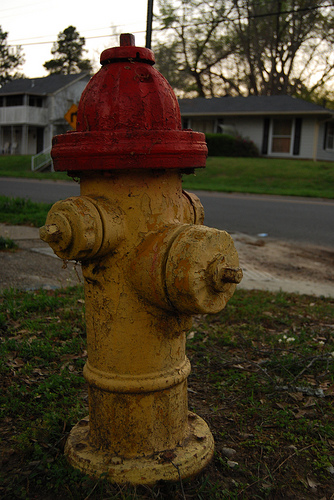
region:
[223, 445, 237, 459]
a dead leaf on the ground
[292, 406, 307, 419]
a dead leaf on the ground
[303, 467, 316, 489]
a dead leaf on the ground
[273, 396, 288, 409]
a dead leaf on the ground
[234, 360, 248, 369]
a dead leaf on the ground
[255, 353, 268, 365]
a dead leaf on the ground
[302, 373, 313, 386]
a dead leaf on the ground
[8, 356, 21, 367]
a dead leaf on the ground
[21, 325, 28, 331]
a dead leaf on the ground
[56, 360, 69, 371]
a dead leaf on the ground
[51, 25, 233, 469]
a red and yellow fire hydrant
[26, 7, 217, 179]
red top of a fire hydrant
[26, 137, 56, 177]
a white hand rail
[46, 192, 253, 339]
a fire hydrant with the paint coming off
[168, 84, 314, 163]
a white house with black shutters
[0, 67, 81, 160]
a two story house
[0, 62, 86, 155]
a house with two porches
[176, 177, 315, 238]
a paved road way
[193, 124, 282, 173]
a hedge bush in front of a house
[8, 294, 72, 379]
brown leaves on the ground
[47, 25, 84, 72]
a tree in a distance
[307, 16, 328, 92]
a tree in a distance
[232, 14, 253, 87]
a tree in a distance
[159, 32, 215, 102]
a tree in a distance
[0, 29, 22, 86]
a tree in a distance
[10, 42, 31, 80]
a tree in a distance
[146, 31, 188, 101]
a tree in a distance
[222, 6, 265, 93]
a tree in a distance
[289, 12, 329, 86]
a tree in a distance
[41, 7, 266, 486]
a fire hydrant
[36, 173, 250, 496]
Bottom portion of fire hydrant painted yellow.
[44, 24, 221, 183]
Top portion of fire hydrant painted red.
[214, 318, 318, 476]
Area on ground with grass, dirt and leaves.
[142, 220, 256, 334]
Portion of fire hydrant that accepts hose.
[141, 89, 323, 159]
Single story house with black shutters.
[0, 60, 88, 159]
Two story house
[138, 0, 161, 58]
Utility pole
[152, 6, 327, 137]
Trees behind house.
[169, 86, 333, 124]
Black shingled roof.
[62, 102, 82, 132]
Yellow and black traffic sign.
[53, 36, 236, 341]
Red and yellow fire hydrant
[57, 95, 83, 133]
Yellow and black road sign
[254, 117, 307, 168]
Window with black shutters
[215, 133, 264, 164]
Bushes in front of a house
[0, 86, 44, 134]
Balcony on house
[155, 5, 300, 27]
Power lines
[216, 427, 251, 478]
Pebbles on the ground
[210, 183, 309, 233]
Road in front of a house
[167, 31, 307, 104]
Trees behind a house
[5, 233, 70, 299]
Sidewalk near fire hydrant